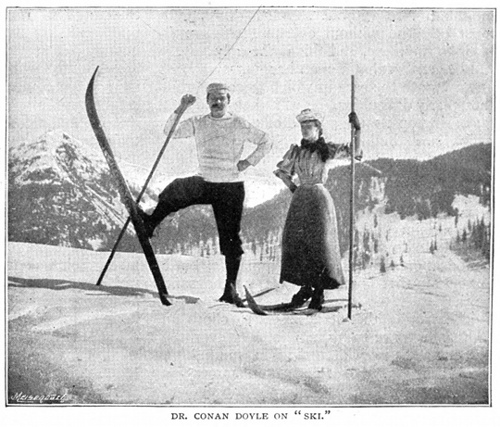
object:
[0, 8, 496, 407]
photo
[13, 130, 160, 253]
mountains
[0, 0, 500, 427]
background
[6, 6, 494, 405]
day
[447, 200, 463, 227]
trees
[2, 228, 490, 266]
horizon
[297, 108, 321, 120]
hat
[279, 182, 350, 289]
skirt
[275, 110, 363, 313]
lady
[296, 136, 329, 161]
scarf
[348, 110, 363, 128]
hand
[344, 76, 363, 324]
ski pole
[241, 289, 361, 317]
skis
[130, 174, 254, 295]
pants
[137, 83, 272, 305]
man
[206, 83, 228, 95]
hat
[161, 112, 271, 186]
shirt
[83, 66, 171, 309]
ski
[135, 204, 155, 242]
foot